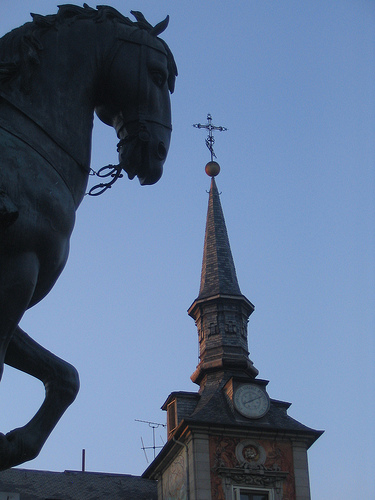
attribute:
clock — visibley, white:
[229, 365, 277, 430]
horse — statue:
[8, 12, 188, 482]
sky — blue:
[242, 49, 282, 99]